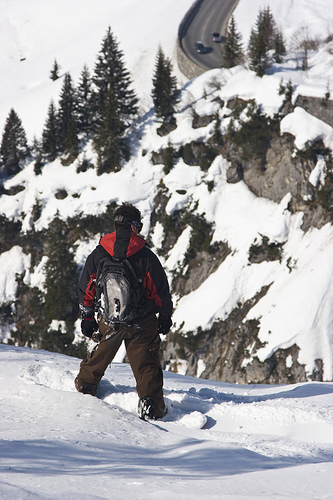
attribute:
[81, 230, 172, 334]
jacket — red, black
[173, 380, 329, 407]
shadow — curved, thin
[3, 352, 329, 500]
snow — deep, white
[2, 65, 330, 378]
mountain — snow-covered, rocky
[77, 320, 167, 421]
pants — brown, red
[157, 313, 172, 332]
glove — black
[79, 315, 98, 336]
glove — black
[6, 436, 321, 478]
shadows — thin, wavy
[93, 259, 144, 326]
backpack — silver, black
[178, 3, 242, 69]
road — paved, elevated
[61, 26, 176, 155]
trees — green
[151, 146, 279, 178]
edges — rough